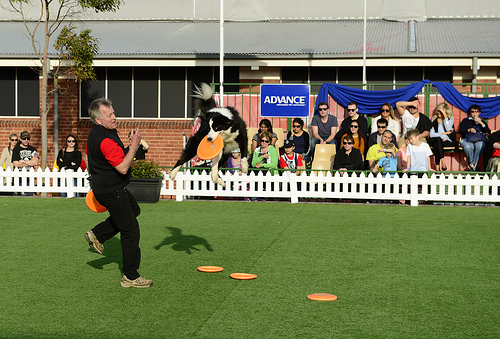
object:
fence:
[0, 167, 500, 207]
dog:
[169, 82, 250, 182]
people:
[457, 104, 492, 172]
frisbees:
[306, 292, 337, 302]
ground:
[0, 194, 500, 339]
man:
[84, 97, 154, 287]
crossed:
[127, 127, 150, 151]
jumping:
[168, 82, 248, 187]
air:
[141, 4, 174, 71]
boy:
[372, 145, 398, 174]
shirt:
[378, 158, 399, 177]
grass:
[0, 194, 499, 339]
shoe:
[120, 275, 153, 288]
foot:
[83, 230, 105, 255]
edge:
[487, 209, 499, 227]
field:
[0, 196, 500, 339]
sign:
[261, 84, 307, 116]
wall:
[0, 90, 196, 170]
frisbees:
[229, 272, 256, 280]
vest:
[85, 125, 132, 190]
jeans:
[91, 187, 141, 280]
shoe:
[84, 230, 104, 255]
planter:
[127, 168, 160, 188]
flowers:
[132, 162, 139, 177]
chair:
[312, 143, 337, 175]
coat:
[229, 157, 244, 174]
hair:
[86, 97, 109, 126]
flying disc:
[196, 133, 223, 159]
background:
[0, 0, 500, 339]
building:
[0, 0, 500, 198]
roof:
[0, 0, 500, 58]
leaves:
[84, 0, 91, 3]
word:
[262, 95, 270, 104]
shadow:
[86, 237, 122, 273]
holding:
[127, 129, 144, 142]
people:
[401, 129, 438, 172]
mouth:
[205, 133, 220, 144]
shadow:
[154, 227, 214, 254]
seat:
[312, 162, 332, 175]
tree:
[0, 0, 116, 168]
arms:
[98, 137, 136, 175]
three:
[196, 265, 338, 300]